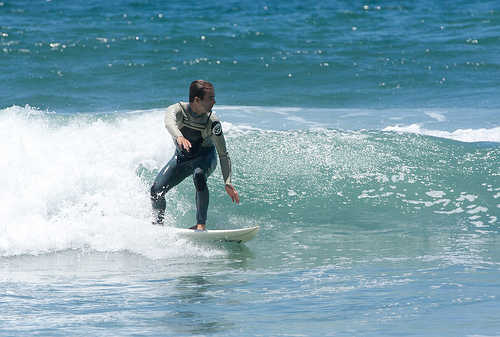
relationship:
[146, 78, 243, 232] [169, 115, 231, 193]
man in suit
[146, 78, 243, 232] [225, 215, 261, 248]
man on board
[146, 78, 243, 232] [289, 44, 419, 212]
man in water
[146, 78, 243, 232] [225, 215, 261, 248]
man on h board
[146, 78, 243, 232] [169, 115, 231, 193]
man wearing suit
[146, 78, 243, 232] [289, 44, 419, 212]
man close to water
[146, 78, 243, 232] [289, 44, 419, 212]
man on water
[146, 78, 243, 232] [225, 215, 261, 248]
man riding board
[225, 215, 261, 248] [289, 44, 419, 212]
board in water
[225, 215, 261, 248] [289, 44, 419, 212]
board on water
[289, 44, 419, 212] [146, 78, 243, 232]
water near man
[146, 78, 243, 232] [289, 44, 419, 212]
man inside water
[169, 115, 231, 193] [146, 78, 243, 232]
suit on man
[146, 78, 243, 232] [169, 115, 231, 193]
man has suit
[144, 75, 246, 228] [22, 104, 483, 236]
man surfing wave